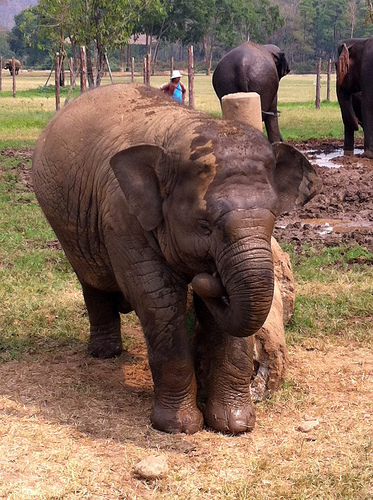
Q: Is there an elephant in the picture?
A: Yes, there is an elephant.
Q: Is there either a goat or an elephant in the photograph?
A: Yes, there is an elephant.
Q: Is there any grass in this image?
A: Yes, there is grass.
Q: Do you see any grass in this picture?
A: Yes, there is grass.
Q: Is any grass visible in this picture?
A: Yes, there is grass.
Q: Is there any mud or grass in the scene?
A: Yes, there is grass.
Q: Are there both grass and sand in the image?
A: No, there is grass but no sand.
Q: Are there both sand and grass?
A: No, there is grass but no sand.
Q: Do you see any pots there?
A: No, there are no pots.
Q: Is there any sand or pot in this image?
A: No, there are no pots or sand.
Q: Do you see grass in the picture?
A: Yes, there is grass.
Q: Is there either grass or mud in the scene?
A: Yes, there is grass.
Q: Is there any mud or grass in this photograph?
A: Yes, there is grass.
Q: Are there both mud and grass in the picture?
A: Yes, there are both grass and mud.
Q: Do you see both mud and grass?
A: Yes, there are both grass and mud.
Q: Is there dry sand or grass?
A: Yes, there is dry grass.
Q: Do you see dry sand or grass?
A: Yes, there is dry grass.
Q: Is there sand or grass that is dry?
A: Yes, the grass is dry.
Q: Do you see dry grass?
A: Yes, there is dry grass.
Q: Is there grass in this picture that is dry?
A: Yes, there is grass that is dry.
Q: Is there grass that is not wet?
A: Yes, there is dry grass.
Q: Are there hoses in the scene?
A: No, there are no hoses.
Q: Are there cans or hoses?
A: No, there are no hoses or cans.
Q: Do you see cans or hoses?
A: No, there are no hoses or cans.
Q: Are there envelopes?
A: No, there are no envelopes.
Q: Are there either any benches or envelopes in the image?
A: No, there are no envelopes or benches.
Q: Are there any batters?
A: No, there are no batters.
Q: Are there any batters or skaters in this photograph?
A: No, there are no batters or skaters.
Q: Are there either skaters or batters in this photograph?
A: No, there are no batters or skaters.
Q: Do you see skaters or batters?
A: No, there are no batters or skaters.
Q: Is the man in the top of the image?
A: Yes, the man is in the top of the image.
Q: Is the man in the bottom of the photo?
A: No, the man is in the top of the image.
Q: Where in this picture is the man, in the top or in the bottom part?
A: The man is in the top of the image.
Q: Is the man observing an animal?
A: Yes, the man is observing an animal.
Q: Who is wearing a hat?
A: The man is wearing a hat.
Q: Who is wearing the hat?
A: The man is wearing a hat.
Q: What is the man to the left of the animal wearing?
A: The man is wearing a hat.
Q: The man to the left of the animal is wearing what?
A: The man is wearing a hat.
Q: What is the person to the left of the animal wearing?
A: The man is wearing a hat.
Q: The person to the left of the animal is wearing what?
A: The man is wearing a hat.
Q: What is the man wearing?
A: The man is wearing a hat.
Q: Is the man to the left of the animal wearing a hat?
A: Yes, the man is wearing a hat.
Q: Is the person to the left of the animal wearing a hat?
A: Yes, the man is wearing a hat.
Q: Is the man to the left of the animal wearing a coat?
A: No, the man is wearing a hat.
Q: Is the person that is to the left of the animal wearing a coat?
A: No, the man is wearing a hat.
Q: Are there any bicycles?
A: No, there are no bicycles.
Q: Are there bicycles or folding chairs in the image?
A: No, there are no bicycles or folding chairs.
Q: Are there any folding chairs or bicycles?
A: No, there are no bicycles or folding chairs.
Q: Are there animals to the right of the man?
A: Yes, there is an animal to the right of the man.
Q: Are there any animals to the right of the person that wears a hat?
A: Yes, there is an animal to the right of the man.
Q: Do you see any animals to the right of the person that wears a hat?
A: Yes, there is an animal to the right of the man.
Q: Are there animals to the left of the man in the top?
A: No, the animal is to the right of the man.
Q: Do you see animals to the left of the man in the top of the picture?
A: No, the animal is to the right of the man.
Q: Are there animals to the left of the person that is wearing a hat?
A: No, the animal is to the right of the man.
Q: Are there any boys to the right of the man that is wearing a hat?
A: No, there is an animal to the right of the man.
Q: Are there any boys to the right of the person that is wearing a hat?
A: No, there is an animal to the right of the man.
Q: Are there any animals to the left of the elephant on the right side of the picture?
A: Yes, there is an animal to the left of the elephant.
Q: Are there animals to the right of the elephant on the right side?
A: No, the animal is to the left of the elephant.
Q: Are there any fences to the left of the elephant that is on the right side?
A: No, there is an animal to the left of the elephant.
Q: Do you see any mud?
A: Yes, there is mud.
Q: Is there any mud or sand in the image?
A: Yes, there is mud.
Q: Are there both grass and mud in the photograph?
A: Yes, there are both mud and grass.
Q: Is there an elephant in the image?
A: Yes, there is an elephant.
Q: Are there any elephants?
A: Yes, there is an elephant.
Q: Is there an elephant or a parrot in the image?
A: Yes, there is an elephant.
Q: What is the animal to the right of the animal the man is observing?
A: The animal is an elephant.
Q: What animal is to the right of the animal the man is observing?
A: The animal is an elephant.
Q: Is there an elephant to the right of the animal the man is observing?
A: Yes, there is an elephant to the right of the animal.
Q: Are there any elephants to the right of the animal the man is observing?
A: Yes, there is an elephant to the right of the animal.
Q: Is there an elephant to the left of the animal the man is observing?
A: No, the elephant is to the right of the animal.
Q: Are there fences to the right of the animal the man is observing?
A: No, there is an elephant to the right of the animal.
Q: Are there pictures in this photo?
A: No, there are no pictures.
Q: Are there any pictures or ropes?
A: No, there are no pictures or ropes.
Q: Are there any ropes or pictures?
A: No, there are no pictures or ropes.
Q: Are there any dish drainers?
A: No, there are no dish drainers.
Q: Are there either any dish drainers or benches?
A: No, there are no dish drainers or benches.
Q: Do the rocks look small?
A: Yes, the rocks are small.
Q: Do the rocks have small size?
A: Yes, the rocks are small.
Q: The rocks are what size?
A: The rocks are small.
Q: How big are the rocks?
A: The rocks are small.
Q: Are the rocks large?
A: No, the rocks are small.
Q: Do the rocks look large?
A: No, the rocks are small.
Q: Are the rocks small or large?
A: The rocks are small.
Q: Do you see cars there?
A: No, there are no cars.